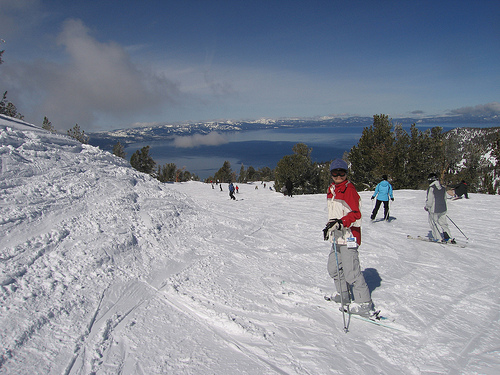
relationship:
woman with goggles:
[322, 158, 377, 323] [312, 162, 368, 179]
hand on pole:
[316, 217, 352, 252] [321, 232, 354, 334]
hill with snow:
[8, 91, 488, 361] [20, 117, 485, 369]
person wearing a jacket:
[322, 157, 376, 317] [325, 178, 362, 245]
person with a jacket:
[366, 171, 400, 222] [371, 184, 392, 203]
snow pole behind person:
[445, 212, 468, 242] [424, 172, 454, 244]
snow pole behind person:
[426, 209, 447, 244] [424, 172, 454, 244]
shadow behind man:
[356, 264, 386, 294] [304, 143, 395, 337]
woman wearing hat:
[322, 158, 377, 323] [326, 157, 347, 172]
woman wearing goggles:
[322, 158, 377, 323] [319, 164, 356, 182]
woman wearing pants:
[322, 158, 377, 323] [326, 241, 371, 305]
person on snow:
[366, 171, 400, 222] [4, 101, 498, 371]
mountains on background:
[88, 115, 492, 140] [91, 108, 497, 152]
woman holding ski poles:
[322, 158, 377, 323] [328, 233, 350, 336]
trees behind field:
[330, 106, 498, 190] [154, 177, 498, 373]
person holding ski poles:
[322, 157, 376, 317] [328, 233, 350, 336]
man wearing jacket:
[416, 166, 456, 245] [423, 183, 444, 215]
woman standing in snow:
[370, 174, 394, 224] [2, 187, 497, 372]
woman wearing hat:
[322, 158, 377, 323] [318, 155, 359, 178]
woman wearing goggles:
[322, 158, 377, 323] [328, 164, 349, 183]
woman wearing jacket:
[322, 158, 377, 323] [320, 183, 365, 249]